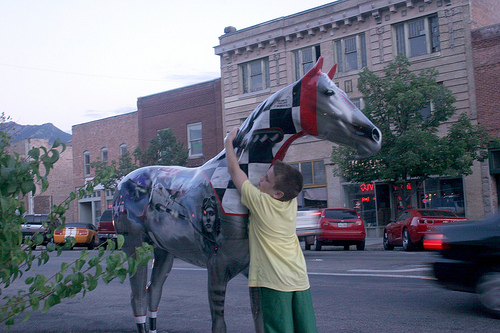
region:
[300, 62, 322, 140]
Red stripe around horse's head.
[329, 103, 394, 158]
Horse has gray face.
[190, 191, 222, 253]
Picture of person on horse.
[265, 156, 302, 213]
Person has brown hair.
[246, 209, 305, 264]
Person wearing white shirt.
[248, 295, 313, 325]
Person wearing green shorts.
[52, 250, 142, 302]
Green leaves on tree near horse.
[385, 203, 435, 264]
Red car parked near tree.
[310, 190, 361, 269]
Red car parked across street.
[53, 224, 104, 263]
Yellow car parked across street.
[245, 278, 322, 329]
Boy wearing pants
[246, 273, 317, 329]
Boy is wearing pants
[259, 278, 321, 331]
Boy wearing green pants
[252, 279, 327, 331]
Boy is wearing green pants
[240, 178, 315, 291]
Boy wearing a shirt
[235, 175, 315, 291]
Boy is wearing a shirt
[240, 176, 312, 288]
Boy wearing a white shirt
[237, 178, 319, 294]
Boy is wearing a white shirt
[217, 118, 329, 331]
Boy hugging a statue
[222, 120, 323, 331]
Boy hugging a horse statue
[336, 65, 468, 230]
a tree along the street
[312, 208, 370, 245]
a red car parked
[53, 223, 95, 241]
an orange car parked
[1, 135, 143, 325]
a bush next to the horse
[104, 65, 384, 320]
a grey horse statue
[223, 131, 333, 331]
a boy hugging a horse statue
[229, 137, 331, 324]
a boy wearing a yellow shirt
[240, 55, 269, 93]
a window in the building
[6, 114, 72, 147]
a mountain in the background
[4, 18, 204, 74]
the cloudy sky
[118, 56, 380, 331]
horse sculpture on street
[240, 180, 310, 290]
yellow cotton tee shirt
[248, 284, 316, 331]
green cotton kids shorts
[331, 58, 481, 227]
tree with green leaves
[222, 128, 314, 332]
boy hugging horse sculpture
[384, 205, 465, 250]
red car on street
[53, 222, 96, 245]
orange car on street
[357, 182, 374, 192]
lit sign in window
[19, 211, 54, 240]
silver car on street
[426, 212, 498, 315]
black car on street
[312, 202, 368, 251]
Red car near curb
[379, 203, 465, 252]
Red car near curb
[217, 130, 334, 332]
Boy wearing a yellow shirt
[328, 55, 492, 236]
Tree in front of building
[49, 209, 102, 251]
Orange car near curb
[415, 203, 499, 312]
Black car on the street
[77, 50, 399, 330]
Horse statue on the sidewalk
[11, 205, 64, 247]
Pickup truck in the background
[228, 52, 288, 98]
Window on the building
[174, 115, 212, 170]
Window on the building